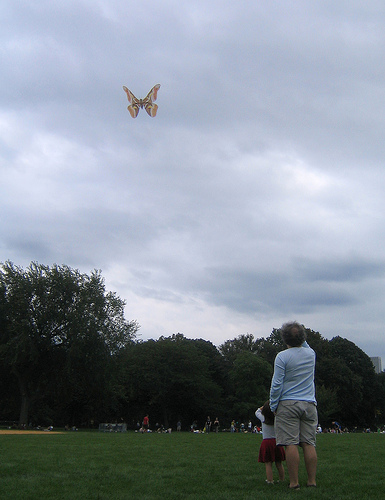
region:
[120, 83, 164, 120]
an orange and white butterfly kite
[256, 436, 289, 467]
a red skirt on a little girl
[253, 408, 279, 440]
a white shirt on a little girl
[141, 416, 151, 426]
a red shirt on a person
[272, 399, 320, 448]
tan shortson a person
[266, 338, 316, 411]
a pale blue long sleeved shirt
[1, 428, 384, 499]
a green grassy field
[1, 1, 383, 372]
a cloudy gray blue sky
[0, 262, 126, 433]
a large tree next to a field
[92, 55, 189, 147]
this is a butterfly kite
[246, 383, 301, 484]
she is flying the kite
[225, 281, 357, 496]
a man and his daughter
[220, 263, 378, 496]
two people in a park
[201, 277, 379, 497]
two people flying a kite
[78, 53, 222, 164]
the kite is shaped like a butterfly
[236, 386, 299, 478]
she is wearing a red skirt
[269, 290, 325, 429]
he is wearing a blue shirt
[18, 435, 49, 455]
green grass on ground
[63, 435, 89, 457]
green grass on ground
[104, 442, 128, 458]
green grass on ground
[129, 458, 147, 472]
green grass on ground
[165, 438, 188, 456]
green grass on ground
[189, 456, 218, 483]
green grass on ground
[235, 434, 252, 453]
green grass on ground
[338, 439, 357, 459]
green grass on ground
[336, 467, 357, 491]
green grass on ground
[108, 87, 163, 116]
orange and white kite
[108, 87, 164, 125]
kite has butterfly shape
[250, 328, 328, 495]
people standing on grass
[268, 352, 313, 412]
man has blue shirt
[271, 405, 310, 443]
man has grey shorts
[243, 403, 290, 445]
girl has white shirt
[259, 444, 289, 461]
girl has red dress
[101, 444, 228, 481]
grass is thick and green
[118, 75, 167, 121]
a kite that looks like a butterfly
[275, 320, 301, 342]
the head of a grandmother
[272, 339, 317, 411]
the blue shirt of a grandmother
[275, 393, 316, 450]
the shorts of a grandmother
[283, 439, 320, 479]
the legs of a grandmother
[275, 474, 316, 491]
the feet of a grandmother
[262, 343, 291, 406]
the arm of a grandmother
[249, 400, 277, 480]
a little girl in a skirt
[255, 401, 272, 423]
the hair of a little girl